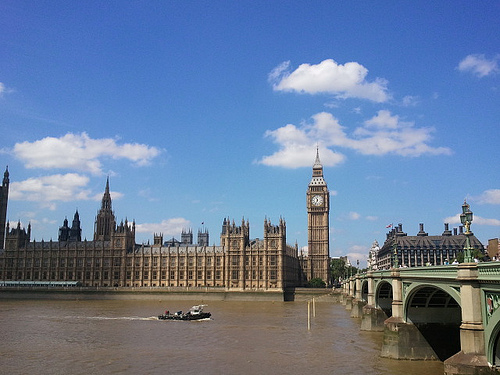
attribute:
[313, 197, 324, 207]
clock — big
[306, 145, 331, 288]
tower — big ben, tall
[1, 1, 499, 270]
sky — blue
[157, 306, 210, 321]
boat — black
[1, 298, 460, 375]
river — large, brown, calm, muddy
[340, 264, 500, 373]
bridge — green, sun-lit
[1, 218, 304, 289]
building — brown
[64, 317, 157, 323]
waves — long